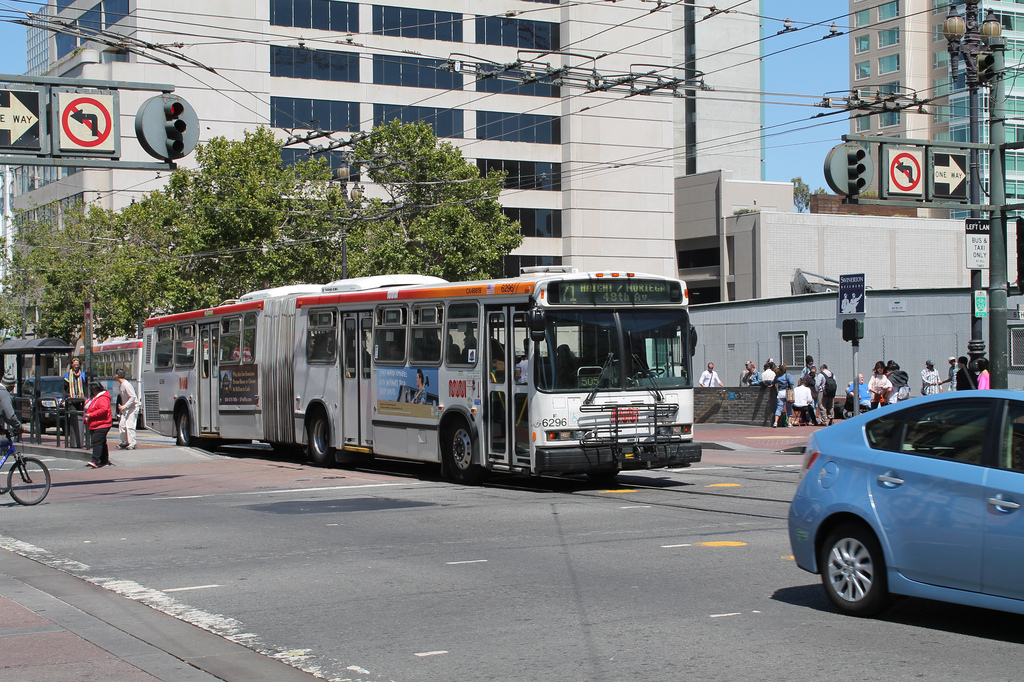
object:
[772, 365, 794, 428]
people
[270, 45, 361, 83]
windows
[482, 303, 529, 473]
door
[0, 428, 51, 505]
bicycle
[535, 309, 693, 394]
windshield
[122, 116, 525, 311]
trees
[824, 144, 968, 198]
street signs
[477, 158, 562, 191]
window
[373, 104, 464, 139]
window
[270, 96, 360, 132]
window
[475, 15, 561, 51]
window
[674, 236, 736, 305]
window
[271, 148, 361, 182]
window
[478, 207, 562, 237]
window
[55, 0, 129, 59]
window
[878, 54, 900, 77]
window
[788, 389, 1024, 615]
car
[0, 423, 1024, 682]
street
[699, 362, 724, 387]
person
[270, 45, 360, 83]
window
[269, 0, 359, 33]
window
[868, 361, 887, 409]
person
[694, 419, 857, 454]
sidewalk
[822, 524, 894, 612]
tire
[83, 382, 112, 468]
handle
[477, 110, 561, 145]
window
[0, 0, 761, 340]
building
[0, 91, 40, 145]
white arrow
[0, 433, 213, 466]
sidewalk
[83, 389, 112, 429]
coat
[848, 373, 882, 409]
person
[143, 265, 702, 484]
bus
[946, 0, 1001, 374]
post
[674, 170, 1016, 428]
building